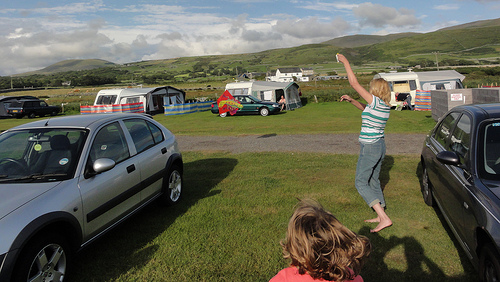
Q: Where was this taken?
A: Field.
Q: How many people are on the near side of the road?
A: 2.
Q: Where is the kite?
A: Over the road.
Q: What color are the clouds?
A: Gray.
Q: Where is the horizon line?
A: Over the hills.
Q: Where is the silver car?
A: Bottom left corner.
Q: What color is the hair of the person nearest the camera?
A: Blonde.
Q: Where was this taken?
A: Field.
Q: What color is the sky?
A: Blue.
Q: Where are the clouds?
A: In the sky.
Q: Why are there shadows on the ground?
A: Sunny.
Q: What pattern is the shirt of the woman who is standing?
A: Striped.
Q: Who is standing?
A: Woman in the striped shirt.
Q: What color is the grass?
A: Green.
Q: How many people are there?
A: 3.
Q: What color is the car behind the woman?
A: Black.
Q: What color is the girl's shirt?
A: Red.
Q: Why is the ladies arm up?
A: Flying a kite.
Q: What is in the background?
A: Mountains.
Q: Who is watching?
A: A woman.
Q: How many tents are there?
A: Three.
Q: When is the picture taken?
A: Day time.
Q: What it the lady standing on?
A: Grass.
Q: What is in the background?
A: A house.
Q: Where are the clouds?
A: In the sky.